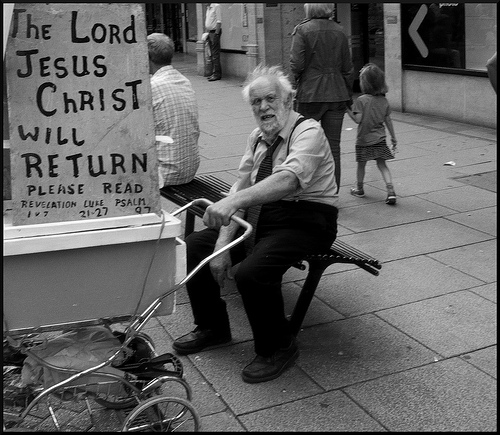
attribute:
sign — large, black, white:
[2, 2, 170, 231]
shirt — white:
[246, 139, 320, 175]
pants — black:
[172, 194, 342, 341]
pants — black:
[187, 205, 351, 331]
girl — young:
[349, 63, 397, 206]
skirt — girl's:
[340, 128, 409, 165]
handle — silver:
[121, 197, 253, 328]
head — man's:
[238, 60, 297, 140]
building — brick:
[379, 29, 498, 131]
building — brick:
[177, 28, 364, 82]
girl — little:
[346, 62, 407, 206]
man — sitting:
[146, 22, 203, 193]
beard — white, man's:
[252, 102, 296, 136]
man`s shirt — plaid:
[148, 65, 199, 189]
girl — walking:
[348, 55, 398, 213]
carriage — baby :
[4, 197, 252, 434]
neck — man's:
[251, 108, 303, 141]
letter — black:
[12, 47, 37, 79]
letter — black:
[67, 8, 93, 45]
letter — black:
[33, 81, 60, 115]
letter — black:
[16, 150, 45, 178]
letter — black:
[18, 122, 43, 140]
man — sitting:
[173, 62, 337, 382]